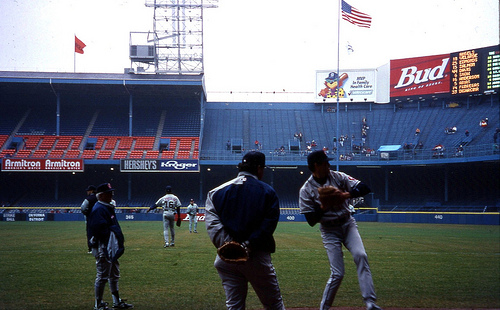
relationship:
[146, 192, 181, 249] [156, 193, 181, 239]
player in uniform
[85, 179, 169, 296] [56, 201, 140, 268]
man in uniform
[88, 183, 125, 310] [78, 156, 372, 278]
man of team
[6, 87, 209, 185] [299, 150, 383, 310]
upper deck of man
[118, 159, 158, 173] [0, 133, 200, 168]
banner along deck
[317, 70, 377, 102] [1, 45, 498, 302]
advertisement on stadium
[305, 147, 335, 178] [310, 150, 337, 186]
hat on head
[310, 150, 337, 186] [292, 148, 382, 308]
head of man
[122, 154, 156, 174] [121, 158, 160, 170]
hersheys written on a banner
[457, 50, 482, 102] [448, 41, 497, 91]
names on scoreboard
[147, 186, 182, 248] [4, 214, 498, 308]
player standing on grass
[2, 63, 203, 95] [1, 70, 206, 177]
awning on upper deck